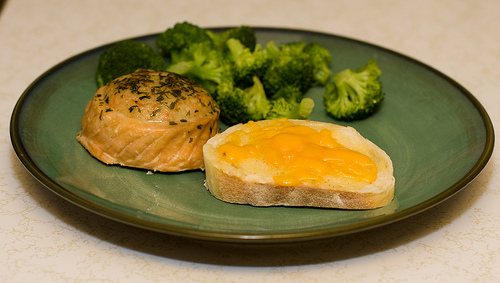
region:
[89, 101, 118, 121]
Small specks on a peice of food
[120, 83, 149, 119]
Small specks on a peice of food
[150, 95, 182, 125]
Small specks on a peice of food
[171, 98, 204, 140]
Small specks on a peice of food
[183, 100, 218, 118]
Small specks on a peice of food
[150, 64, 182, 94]
Small specks on a peice of food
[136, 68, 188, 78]
Small specks on a peice of food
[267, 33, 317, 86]
Green veggie on a plate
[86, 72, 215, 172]
A piece of salmon sprinkled with herbs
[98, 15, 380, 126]
A pile of boiled broccoli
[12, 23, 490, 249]
A green plate of food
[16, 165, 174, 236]
Rim of a green plate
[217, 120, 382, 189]
Cheese on a piece of bread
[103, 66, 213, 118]
Herbs sprinkled on salmon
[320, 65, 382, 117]
Underside of a head of broccoli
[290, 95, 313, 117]
Stalk on a piece of broccoli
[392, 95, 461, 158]
A green plate of ceramic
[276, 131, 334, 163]
cheese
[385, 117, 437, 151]
the plate is green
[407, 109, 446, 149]
a plate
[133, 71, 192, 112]
seasoning on the meat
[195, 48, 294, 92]
green brocolli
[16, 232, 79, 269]
the counter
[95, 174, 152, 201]
a shadow on the plate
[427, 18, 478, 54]
a white counter top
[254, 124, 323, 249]
There is a piece of bread here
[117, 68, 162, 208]
There is a piece of tuna here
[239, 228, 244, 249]
There is a green border that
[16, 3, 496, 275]
The plate of food on the counter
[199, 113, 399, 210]
A slice of bread on the plate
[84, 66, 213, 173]
A piece of fish on the plate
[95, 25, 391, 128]
A side dish of broccoli on the plate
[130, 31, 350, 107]
Broccolli is the color green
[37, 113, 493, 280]
The plate is the color green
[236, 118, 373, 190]
The cheese on the bread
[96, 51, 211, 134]
The herbs on the fish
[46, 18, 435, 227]
The food is ready to eat